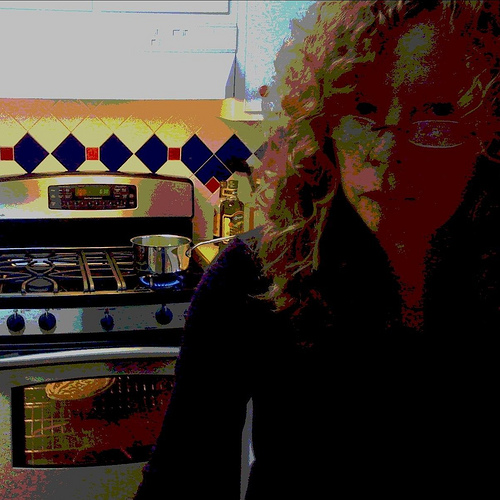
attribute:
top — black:
[173, 222, 481, 479]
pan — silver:
[129, 221, 249, 277]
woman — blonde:
[128, 0, 499, 498]